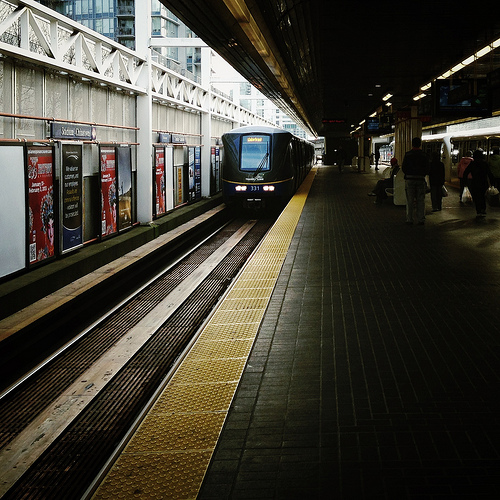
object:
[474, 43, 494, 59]
overhead light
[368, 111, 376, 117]
overhead light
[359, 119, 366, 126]
overhead light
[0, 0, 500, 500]
train station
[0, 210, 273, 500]
tracks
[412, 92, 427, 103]
lights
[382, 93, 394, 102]
lights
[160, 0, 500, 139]
ceiling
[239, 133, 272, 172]
window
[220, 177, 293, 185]
stripe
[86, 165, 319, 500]
part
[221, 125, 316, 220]
train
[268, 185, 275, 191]
headlight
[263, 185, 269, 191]
headlight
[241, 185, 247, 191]
headlight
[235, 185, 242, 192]
headlight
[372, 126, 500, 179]
train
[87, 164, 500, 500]
platform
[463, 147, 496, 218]
person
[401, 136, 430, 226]
person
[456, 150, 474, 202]
person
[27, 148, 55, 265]
advertising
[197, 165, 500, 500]
side walk.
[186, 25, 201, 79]
buildings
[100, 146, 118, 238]
advertisement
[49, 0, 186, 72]
building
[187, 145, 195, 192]
banner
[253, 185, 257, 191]
numbers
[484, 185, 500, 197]
bag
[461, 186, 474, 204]
bag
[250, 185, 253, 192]
number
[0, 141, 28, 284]
panels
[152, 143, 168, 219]
banner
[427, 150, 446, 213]
people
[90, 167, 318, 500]
yellow area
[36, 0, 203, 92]
left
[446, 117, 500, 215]
right